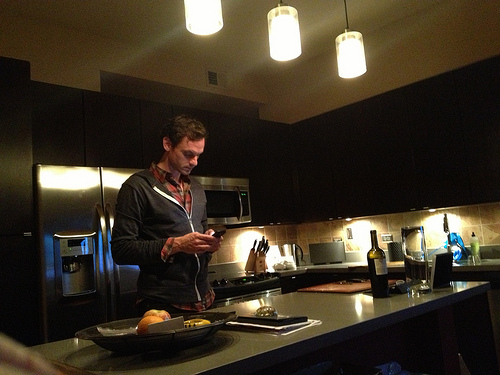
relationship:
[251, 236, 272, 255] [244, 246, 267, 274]
knives in wooden block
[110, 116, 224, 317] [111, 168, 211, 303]
man wearing jacket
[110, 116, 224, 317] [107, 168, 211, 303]
man wearing jacket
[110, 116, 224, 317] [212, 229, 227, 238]
man holding cell phone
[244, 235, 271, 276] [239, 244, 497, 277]
knife holder on countertop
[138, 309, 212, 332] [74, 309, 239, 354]
fruit in bowl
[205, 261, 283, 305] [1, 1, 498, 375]
stove in kitchen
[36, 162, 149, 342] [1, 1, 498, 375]
refrigerator in kitchen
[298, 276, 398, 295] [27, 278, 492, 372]
cutting board on countertop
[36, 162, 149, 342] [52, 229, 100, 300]
refrigerator with water and ice maker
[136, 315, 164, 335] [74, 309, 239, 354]
orange in bowl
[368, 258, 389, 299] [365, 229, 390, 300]
wine in bottle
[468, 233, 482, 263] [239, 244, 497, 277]
bottle on countertop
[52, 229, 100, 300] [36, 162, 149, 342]
ice and water maker on refrigerator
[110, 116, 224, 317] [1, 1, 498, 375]
man in kitchen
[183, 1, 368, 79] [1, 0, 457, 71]
lights in ceiling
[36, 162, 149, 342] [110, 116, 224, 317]
refrigerator behind man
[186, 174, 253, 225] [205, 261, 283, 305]
microwave above stove